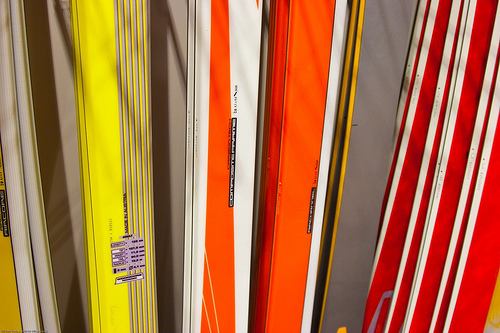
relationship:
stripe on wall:
[70, 1, 160, 331] [85, 179, 136, 330]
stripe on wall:
[185, 116, 204, 301] [149, 99, 276, 323]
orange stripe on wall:
[194, 1, 236, 331] [192, 24, 312, 325]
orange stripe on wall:
[264, 0, 334, 332] [192, 24, 312, 325]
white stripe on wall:
[234, 131, 256, 250] [165, 4, 286, 330]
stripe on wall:
[316, 5, 388, 331] [21, 27, 464, 297]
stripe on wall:
[182, 3, 265, 329] [4, 3, 499, 331]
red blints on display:
[355, 0, 497, 332] [1, 3, 494, 331]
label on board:
[111, 234, 146, 285] [79, 64, 114, 308]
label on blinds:
[108, 231, 148, 288] [55, 4, 173, 329]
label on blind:
[302, 178, 316, 236] [262, 2, 352, 332]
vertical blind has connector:
[156, 12, 498, 283] [408, 2, 488, 318]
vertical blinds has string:
[81, 5, 498, 330] [202, 245, 224, 331]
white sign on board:
[227, 116, 238, 209] [166, 4, 258, 331]